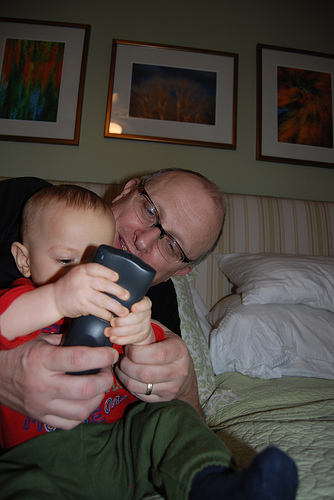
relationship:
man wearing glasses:
[2, 165, 228, 432] [132, 178, 194, 264]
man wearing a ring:
[0, 165, 228, 432] [140, 378, 158, 415]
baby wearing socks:
[3, 181, 300, 498] [179, 456, 291, 496]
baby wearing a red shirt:
[3, 181, 300, 498] [1, 279, 164, 446]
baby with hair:
[3, 181, 300, 498] [33, 179, 105, 208]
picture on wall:
[255, 41, 333, 170] [1, 1, 333, 202]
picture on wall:
[103, 38, 238, 152] [1, 1, 333, 202]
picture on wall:
[0, 14, 90, 145] [1, 1, 333, 202]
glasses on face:
[132, 174, 198, 264] [113, 190, 180, 277]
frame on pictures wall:
[252, 40, 333, 169] [0, 0, 334, 200]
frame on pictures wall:
[102, 37, 239, 151] [0, 0, 334, 200]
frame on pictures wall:
[0, 16, 91, 147] [0, 0, 334, 200]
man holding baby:
[2, 165, 228, 432] [3, 181, 300, 498]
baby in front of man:
[0, 181, 296, 500] [2, 165, 228, 432]